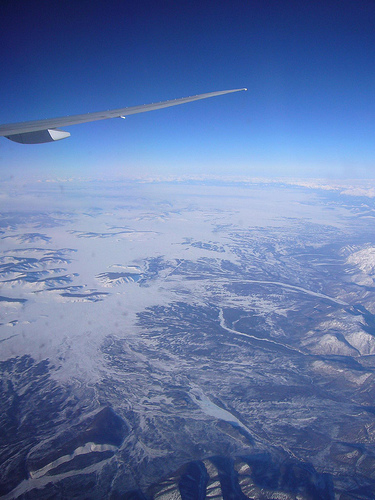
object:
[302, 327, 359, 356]
mountain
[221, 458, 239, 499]
valley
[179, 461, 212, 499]
mountain ravines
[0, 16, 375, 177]
sky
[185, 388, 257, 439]
water valley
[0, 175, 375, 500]
earth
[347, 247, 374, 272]
mountains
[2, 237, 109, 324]
sunshine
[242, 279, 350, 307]
river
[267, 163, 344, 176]
clouds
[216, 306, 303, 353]
frozen river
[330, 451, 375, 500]
valley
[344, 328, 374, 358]
mountain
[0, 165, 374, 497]
range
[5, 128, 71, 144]
vent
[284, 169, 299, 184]
bag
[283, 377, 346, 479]
water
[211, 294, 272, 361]
water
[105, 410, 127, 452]
rocky valley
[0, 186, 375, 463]
snow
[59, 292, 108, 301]
mountains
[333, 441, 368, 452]
shadow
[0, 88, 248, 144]
airplane